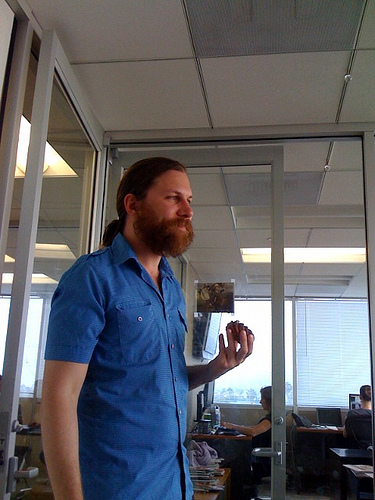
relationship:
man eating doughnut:
[44, 125, 270, 492] [212, 317, 276, 339]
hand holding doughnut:
[213, 327, 266, 367] [212, 317, 276, 339]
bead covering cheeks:
[133, 212, 170, 237] [150, 199, 171, 216]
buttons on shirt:
[157, 301, 192, 443] [40, 255, 204, 451]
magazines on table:
[183, 455, 225, 490] [193, 463, 242, 499]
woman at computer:
[245, 378, 284, 468] [198, 371, 223, 420]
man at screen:
[44, 125, 270, 492] [246, 190, 364, 462]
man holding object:
[44, 125, 270, 492] [212, 317, 276, 339]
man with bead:
[44, 125, 270, 492] [134, 203, 195, 262]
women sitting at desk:
[233, 387, 281, 456] [204, 430, 246, 449]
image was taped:
[191, 274, 241, 320] [224, 273, 240, 283]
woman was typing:
[245, 378, 284, 468] [222, 414, 248, 431]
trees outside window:
[213, 386, 270, 402] [220, 299, 361, 328]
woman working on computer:
[245, 378, 284, 468] [198, 371, 223, 420]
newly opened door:
[226, 179, 316, 431] [268, 175, 332, 491]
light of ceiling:
[237, 239, 364, 278] [120, 38, 367, 268]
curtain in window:
[285, 290, 365, 405] [220, 299, 361, 328]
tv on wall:
[198, 303, 223, 360] [184, 272, 246, 358]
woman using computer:
[245, 378, 284, 468] [198, 371, 223, 420]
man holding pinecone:
[44, 125, 270, 492] [190, 420, 206, 437]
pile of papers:
[188, 458, 220, 498] [194, 441, 221, 489]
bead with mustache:
[134, 203, 195, 262] [163, 212, 198, 231]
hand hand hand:
[209, 316, 256, 388] [209, 316, 256, 388]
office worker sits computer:
[341, 380, 373, 447] [343, 390, 368, 410]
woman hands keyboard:
[245, 378, 284, 468] [213, 421, 246, 442]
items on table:
[184, 442, 239, 481] [193, 463, 242, 499]